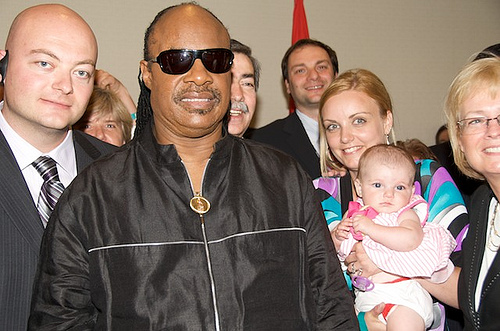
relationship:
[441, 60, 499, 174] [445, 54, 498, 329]
hair of a woman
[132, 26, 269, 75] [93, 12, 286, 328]
sunglasses worn by man